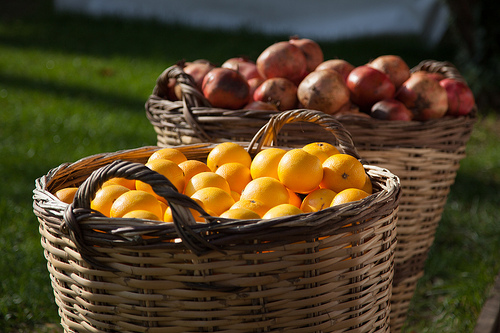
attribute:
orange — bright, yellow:
[138, 136, 377, 199]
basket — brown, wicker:
[39, 153, 388, 311]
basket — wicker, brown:
[154, 60, 470, 240]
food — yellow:
[85, 158, 301, 222]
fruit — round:
[235, 152, 326, 196]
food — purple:
[252, 28, 396, 93]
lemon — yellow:
[270, 151, 325, 194]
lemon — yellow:
[276, 143, 321, 194]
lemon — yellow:
[33, 130, 407, 325]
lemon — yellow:
[107, 185, 163, 215]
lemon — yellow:
[204, 129, 246, 170]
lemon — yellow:
[321, 147, 367, 190]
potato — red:
[347, 61, 397, 108]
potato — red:
[253, 27, 303, 81]